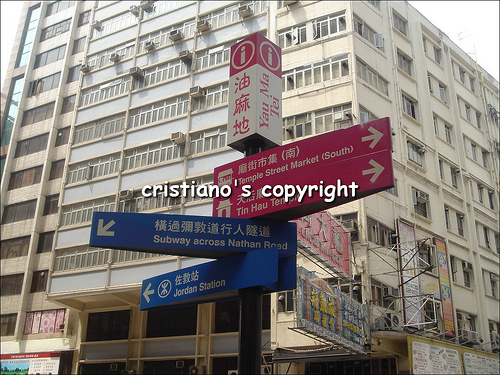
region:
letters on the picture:
[115, 147, 392, 231]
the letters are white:
[125, 162, 375, 214]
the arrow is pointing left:
[120, 267, 167, 307]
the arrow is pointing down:
[78, 200, 133, 253]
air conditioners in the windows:
[92, 12, 209, 134]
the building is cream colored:
[367, 17, 494, 339]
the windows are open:
[278, 17, 333, 41]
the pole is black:
[222, 289, 271, 368]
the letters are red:
[244, 60, 285, 137]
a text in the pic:
[135, 152, 460, 244]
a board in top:
[128, 257, 328, 316]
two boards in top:
[77, 180, 314, 316]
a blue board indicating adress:
[112, 256, 289, 310]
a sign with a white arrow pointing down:
[96, 195, 311, 275]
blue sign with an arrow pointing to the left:
[115, 273, 315, 310]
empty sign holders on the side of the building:
[400, 229, 443, 359]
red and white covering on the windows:
[22, 305, 77, 345]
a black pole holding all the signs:
[232, 287, 274, 372]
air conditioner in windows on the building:
[103, 41, 237, 157]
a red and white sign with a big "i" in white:
[225, 29, 312, 145]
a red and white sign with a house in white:
[213, 191, 248, 220]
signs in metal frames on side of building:
[303, 268, 377, 364]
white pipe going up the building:
[16, 41, 71, 343]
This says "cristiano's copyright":
[145, 168, 354, 213]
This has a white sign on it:
[423, 335, 439, 373]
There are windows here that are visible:
[64, 250, 81, 300]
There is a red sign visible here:
[236, 22, 343, 156]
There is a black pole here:
[234, 329, 258, 371]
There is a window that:
[438, 131, 454, 166]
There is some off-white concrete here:
[21, 158, 36, 215]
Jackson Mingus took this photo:
[144, 109, 341, 371]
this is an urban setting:
[8, 29, 455, 369]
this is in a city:
[15, 26, 466, 310]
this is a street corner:
[141, 160, 361, 330]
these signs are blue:
[77, 189, 289, 313]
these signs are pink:
[198, 139, 427, 214]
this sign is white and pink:
[245, 34, 354, 192]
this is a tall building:
[31, 30, 479, 295]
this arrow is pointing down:
[70, 196, 134, 237]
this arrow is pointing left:
[115, 260, 165, 305]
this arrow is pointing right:
[330, 111, 425, 198]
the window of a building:
[392, 91, 418, 121]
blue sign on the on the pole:
[85, 207, 292, 254]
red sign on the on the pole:
[208, 125, 395, 207]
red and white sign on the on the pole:
[218, 33, 293, 151]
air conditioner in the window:
[185, 85, 204, 101]